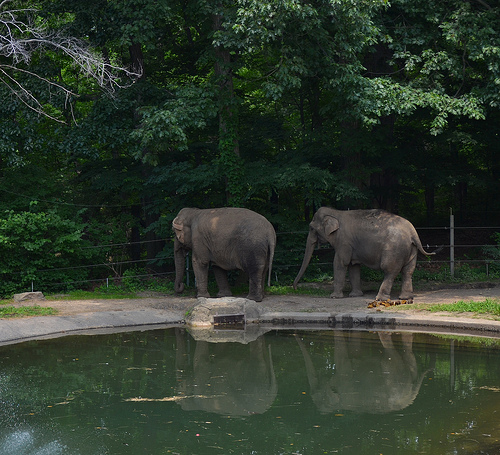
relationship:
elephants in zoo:
[169, 203, 437, 301] [1, 1, 500, 452]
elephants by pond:
[169, 203, 437, 301] [0, 322, 500, 454]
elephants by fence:
[169, 203, 437, 301] [0, 223, 500, 290]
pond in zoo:
[0, 322, 500, 454] [1, 1, 500, 452]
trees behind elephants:
[1, 0, 498, 236] [169, 203, 437, 301]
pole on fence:
[447, 212, 458, 277] [0, 223, 500, 290]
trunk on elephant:
[172, 239, 188, 294] [171, 205, 278, 302]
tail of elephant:
[266, 226, 275, 290] [171, 205, 278, 302]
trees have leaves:
[1, 0, 498, 236] [127, 80, 222, 162]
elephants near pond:
[169, 203, 437, 301] [0, 322, 500, 454]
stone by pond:
[13, 291, 45, 300] [0, 322, 500, 454]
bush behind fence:
[0, 200, 95, 293] [0, 223, 500, 290]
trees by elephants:
[1, 0, 498, 236] [169, 203, 437, 301]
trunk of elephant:
[172, 239, 188, 294] [171, 205, 278, 302]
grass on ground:
[421, 300, 498, 312] [0, 279, 499, 334]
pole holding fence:
[447, 212, 458, 277] [0, 223, 500, 290]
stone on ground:
[13, 291, 45, 300] [0, 279, 499, 334]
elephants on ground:
[169, 203, 437, 301] [0, 279, 499, 334]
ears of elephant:
[320, 214, 339, 237] [292, 206, 436, 300]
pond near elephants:
[0, 322, 500, 454] [169, 203, 437, 301]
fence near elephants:
[0, 223, 500, 290] [169, 203, 437, 301]